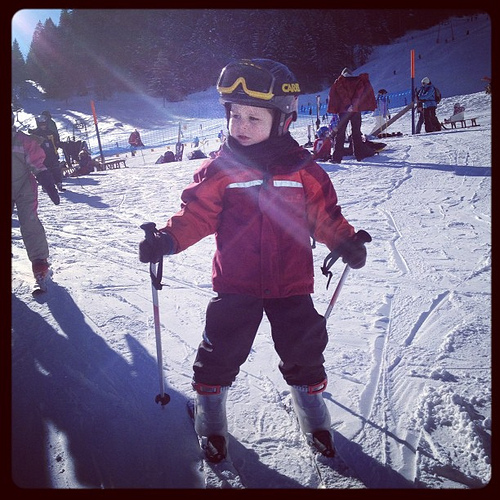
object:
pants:
[192, 294, 329, 392]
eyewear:
[215, 60, 274, 102]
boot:
[289, 378, 338, 457]